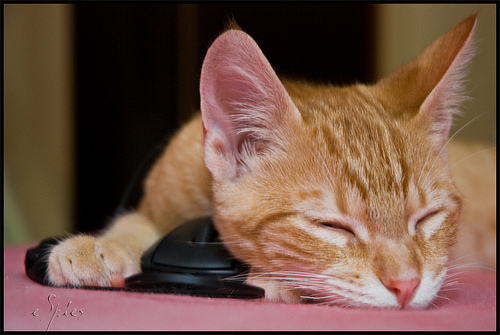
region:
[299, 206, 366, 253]
The right eye of a cat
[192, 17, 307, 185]
The right ear of a cat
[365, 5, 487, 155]
The left ear of a cat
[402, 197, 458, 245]
The left eye of a cat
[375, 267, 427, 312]
The nose of a cat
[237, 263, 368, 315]
The whiskers of a cat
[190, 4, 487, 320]
The face of a cat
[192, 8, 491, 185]
A pair of cat's ears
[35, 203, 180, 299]
A cat's right paw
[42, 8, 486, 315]
A sleeping cat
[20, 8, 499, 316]
a brown cat is sleeping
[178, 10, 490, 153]
pointy ears of cat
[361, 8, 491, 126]
outside part of ear is brown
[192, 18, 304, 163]
inside part of ear is pink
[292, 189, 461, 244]
eyes of cat are closed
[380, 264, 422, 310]
pinky nose of cat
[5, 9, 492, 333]
cat is on a pink surface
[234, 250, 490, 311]
whiskers of car are white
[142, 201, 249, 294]
black mouse of computer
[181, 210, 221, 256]
wheel of mouse of computer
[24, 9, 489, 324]
a sleeping cat next to the computer mouse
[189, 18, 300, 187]
an ear of the cat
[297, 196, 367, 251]
a closed eye of the cat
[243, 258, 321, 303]
white whiskers of the cat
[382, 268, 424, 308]
a nose of the sleeping cat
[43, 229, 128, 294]
a paw of the cat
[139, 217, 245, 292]
a black mouse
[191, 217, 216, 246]
a scroll button of the mouse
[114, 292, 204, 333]
a pink blanket the cat is sleeping on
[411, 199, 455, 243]
a shut eye of the cat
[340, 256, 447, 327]
Nose of a cat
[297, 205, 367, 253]
Eye of a cat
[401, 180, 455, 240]
Eye of a cat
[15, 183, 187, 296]
Leg of a cat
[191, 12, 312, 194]
Ear of a cat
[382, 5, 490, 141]
Ear of a cat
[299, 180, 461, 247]
Eyes of a cat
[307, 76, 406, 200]
Fur of a cat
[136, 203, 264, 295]
Mouse of a computer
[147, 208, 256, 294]
This is a black mouse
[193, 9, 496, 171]
orange cat with pink ears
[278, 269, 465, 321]
cat biting into pink mousepad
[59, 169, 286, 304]
cat sleeping on mouse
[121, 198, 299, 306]
right cheek leaning on mouse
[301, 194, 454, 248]
cat's eyes closed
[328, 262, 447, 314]
pink and white nose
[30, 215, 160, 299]
right paw surrounding side of mouse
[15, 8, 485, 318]
cat leaning on black mouse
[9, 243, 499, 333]
black mouse on pink pad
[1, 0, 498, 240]
blurry background behind cat